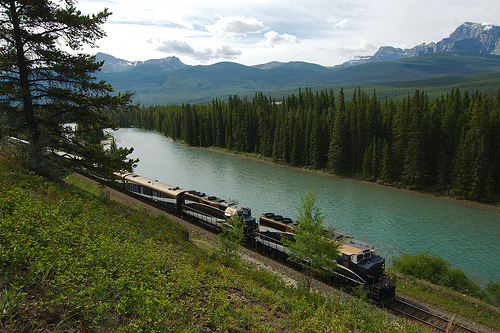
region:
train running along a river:
[6, 133, 411, 305]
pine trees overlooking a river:
[0, 56, 138, 193]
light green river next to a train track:
[59, 119, 497, 299]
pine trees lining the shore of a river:
[110, 82, 496, 209]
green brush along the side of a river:
[390, 244, 496, 304]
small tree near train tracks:
[273, 189, 340, 296]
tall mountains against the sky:
[6, 12, 496, 92]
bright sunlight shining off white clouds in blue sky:
[41, 1, 441, 64]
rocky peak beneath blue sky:
[431, 19, 496, 57]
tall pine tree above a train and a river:
[1, 3, 140, 183]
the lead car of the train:
[258, 200, 399, 307]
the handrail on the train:
[376, 263, 396, 288]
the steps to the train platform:
[369, 281, 383, 298]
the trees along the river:
[198, 83, 498, 190]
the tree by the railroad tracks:
[284, 188, 345, 287]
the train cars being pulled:
[122, 166, 254, 237]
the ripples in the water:
[370, 201, 454, 245]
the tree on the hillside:
[4, 0, 136, 185]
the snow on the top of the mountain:
[459, 21, 499, 46]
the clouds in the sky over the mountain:
[156, 16, 314, 56]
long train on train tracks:
[11, 132, 402, 317]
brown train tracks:
[393, 295, 480, 330]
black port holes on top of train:
[261, 208, 298, 230]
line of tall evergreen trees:
[117, 81, 497, 213]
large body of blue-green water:
[58, 119, 498, 300]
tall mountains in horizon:
[378, 17, 498, 62]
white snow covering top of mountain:
[474, 18, 496, 38]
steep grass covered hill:
[1, 145, 398, 331]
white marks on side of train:
[258, 220, 364, 284]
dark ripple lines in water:
[376, 203, 434, 240]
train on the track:
[31, 125, 411, 292]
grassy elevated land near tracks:
[13, 237, 223, 331]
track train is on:
[396, 295, 463, 327]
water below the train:
[128, 131, 498, 259]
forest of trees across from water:
[144, 85, 486, 170]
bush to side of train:
[395, 252, 472, 284]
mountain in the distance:
[87, 47, 197, 70]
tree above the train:
[5, 33, 120, 175]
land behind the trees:
[196, 65, 488, 95]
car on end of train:
[254, 212, 412, 297]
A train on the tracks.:
[11, 131, 396, 301]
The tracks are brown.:
[385, 299, 465, 329]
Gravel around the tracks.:
[388, 295, 453, 331]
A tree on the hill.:
[3, 2, 126, 193]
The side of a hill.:
[13, 184, 223, 328]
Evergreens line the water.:
[120, 70, 499, 190]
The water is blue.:
[343, 184, 480, 255]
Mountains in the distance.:
[32, 13, 499, 105]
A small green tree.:
[281, 180, 332, 290]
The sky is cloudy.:
[65, 4, 498, 69]